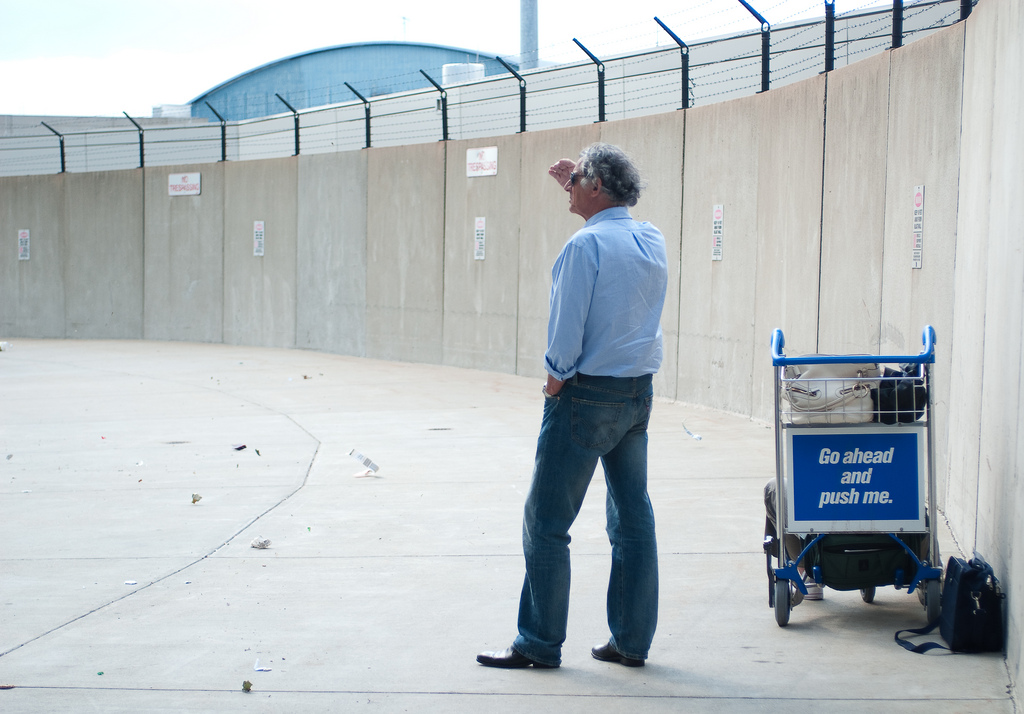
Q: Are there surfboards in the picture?
A: No, there are no surfboards.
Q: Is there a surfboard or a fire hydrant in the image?
A: No, there are no surfboards or fire hydrants.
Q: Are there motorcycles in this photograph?
A: No, there are no motorcycles.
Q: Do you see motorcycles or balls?
A: No, there are no motorcycles or balls.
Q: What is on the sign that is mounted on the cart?
A: The letter is on the sign.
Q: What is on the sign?
A: The letter is on the sign.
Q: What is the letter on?
A: The letter is on the sign.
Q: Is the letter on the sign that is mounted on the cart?
A: Yes, the letter is on the sign.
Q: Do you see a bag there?
A: Yes, there is a bag.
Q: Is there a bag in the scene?
A: Yes, there is a bag.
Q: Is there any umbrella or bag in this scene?
A: Yes, there is a bag.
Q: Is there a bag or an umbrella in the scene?
A: Yes, there is a bag.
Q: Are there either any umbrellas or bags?
A: Yes, there is a bag.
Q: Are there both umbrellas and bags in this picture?
A: No, there is a bag but no umbrellas.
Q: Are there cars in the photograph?
A: No, there are no cars.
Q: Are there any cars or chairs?
A: No, there are no cars or chairs.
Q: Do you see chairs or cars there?
A: No, there are no cars or chairs.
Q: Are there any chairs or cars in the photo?
A: No, there are no cars or chairs.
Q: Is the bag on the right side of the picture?
A: Yes, the bag is on the right of the image.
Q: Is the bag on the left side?
A: No, the bag is on the right of the image.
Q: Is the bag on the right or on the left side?
A: The bag is on the right of the image.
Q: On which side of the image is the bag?
A: The bag is on the right of the image.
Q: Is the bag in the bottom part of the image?
A: Yes, the bag is in the bottom of the image.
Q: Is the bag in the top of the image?
A: No, the bag is in the bottom of the image.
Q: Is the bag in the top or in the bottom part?
A: The bag is in the bottom of the image.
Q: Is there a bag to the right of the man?
A: Yes, there is a bag to the right of the man.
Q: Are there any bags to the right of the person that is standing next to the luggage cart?
A: Yes, there is a bag to the right of the man.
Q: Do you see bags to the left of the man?
A: No, the bag is to the right of the man.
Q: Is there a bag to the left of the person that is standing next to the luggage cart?
A: No, the bag is to the right of the man.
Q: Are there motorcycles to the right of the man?
A: No, there is a bag to the right of the man.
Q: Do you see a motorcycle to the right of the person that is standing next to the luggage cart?
A: No, there is a bag to the right of the man.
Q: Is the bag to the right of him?
A: Yes, the bag is to the right of the man.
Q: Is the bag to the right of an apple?
A: No, the bag is to the right of the man.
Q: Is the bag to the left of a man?
A: No, the bag is to the right of a man.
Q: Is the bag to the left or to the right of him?
A: The bag is to the right of the man.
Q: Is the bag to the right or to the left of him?
A: The bag is to the right of the man.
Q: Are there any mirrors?
A: No, there are no mirrors.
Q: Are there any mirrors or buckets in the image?
A: No, there are no mirrors or buckets.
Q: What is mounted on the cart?
A: The sign is mounted on the cart.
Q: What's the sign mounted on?
A: The sign is mounted on the cart.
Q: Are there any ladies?
A: No, there are no ladies.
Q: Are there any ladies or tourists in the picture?
A: No, there are no ladies or tourists.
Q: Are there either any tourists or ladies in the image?
A: No, there are no ladies or tourists.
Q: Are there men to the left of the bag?
A: Yes, there is a man to the left of the bag.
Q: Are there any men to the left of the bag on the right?
A: Yes, there is a man to the left of the bag.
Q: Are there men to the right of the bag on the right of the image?
A: No, the man is to the left of the bag.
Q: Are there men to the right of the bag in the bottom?
A: No, the man is to the left of the bag.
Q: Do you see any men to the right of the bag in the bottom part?
A: No, the man is to the left of the bag.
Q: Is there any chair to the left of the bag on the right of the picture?
A: No, there is a man to the left of the bag.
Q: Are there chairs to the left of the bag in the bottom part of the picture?
A: No, there is a man to the left of the bag.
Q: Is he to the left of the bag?
A: Yes, the man is to the left of the bag.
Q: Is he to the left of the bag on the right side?
A: Yes, the man is to the left of the bag.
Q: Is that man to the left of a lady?
A: No, the man is to the left of the bag.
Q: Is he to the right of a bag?
A: No, the man is to the left of a bag.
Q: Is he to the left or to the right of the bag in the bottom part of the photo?
A: The man is to the left of the bag.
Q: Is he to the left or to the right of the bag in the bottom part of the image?
A: The man is to the left of the bag.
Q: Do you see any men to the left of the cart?
A: Yes, there is a man to the left of the cart.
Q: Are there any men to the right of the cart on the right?
A: No, the man is to the left of the cart.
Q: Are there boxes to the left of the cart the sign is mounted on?
A: No, there is a man to the left of the cart.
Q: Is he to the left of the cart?
A: Yes, the man is to the left of the cart.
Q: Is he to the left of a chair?
A: No, the man is to the left of the cart.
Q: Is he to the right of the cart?
A: No, the man is to the left of the cart.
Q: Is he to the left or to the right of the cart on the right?
A: The man is to the left of the cart.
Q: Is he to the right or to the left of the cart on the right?
A: The man is to the left of the cart.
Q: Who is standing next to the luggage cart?
A: The man is standing next to the luggage cart.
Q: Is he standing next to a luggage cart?
A: Yes, the man is standing next to a luggage cart.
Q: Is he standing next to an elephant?
A: No, the man is standing next to a luggage cart.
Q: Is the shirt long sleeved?
A: Yes, the shirt is long sleeved.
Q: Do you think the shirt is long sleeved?
A: Yes, the shirt is long sleeved.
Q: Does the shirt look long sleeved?
A: Yes, the shirt is long sleeved.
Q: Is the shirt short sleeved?
A: No, the shirt is long sleeved.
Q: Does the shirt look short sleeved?
A: No, the shirt is long sleeved.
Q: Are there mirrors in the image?
A: No, there are no mirrors.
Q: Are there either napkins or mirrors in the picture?
A: No, there are no mirrors or napkins.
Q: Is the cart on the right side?
A: Yes, the cart is on the right of the image.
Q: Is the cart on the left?
A: No, the cart is on the right of the image.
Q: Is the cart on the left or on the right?
A: The cart is on the right of the image.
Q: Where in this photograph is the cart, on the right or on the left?
A: The cart is on the right of the image.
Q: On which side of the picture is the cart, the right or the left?
A: The cart is on the right of the image.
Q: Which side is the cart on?
A: The cart is on the right of the image.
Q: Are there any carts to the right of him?
A: Yes, there is a cart to the right of the man.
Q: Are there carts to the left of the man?
A: No, the cart is to the right of the man.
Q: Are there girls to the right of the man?
A: No, there is a cart to the right of the man.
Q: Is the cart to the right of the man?
A: Yes, the cart is to the right of the man.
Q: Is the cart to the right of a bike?
A: No, the cart is to the right of the man.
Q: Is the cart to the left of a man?
A: No, the cart is to the right of a man.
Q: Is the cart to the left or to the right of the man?
A: The cart is to the right of the man.